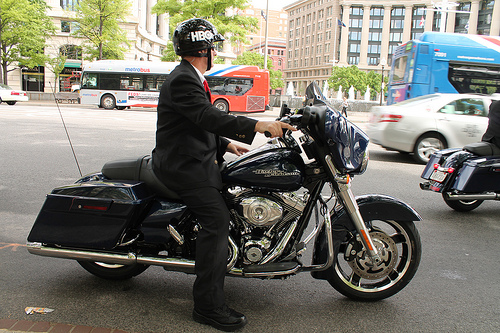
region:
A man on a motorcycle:
[20, 8, 424, 329]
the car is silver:
[373, 96, 495, 150]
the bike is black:
[36, 126, 438, 283]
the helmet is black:
[165, 22, 221, 53]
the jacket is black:
[148, 58, 226, 185]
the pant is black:
[162, 182, 240, 309]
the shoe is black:
[193, 304, 246, 328]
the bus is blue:
[409, 34, 499, 95]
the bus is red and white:
[81, 63, 271, 111]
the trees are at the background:
[3, 2, 384, 94]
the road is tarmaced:
[1, 87, 149, 160]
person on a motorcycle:
[20, 11, 431, 331]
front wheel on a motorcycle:
[308, 190, 427, 310]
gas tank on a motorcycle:
[218, 130, 308, 194]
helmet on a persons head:
[168, 15, 228, 58]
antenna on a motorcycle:
[43, 75, 86, 181]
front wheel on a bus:
[97, 91, 119, 111]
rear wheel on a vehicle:
[411, 130, 452, 166]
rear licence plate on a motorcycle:
[426, 162, 456, 184]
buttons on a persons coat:
[230, 128, 249, 141]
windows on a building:
[343, 2, 386, 67]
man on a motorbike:
[11, 4, 442, 331]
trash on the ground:
[23, 299, 55, 315]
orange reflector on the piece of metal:
[355, 225, 380, 252]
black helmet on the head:
[171, 17, 228, 77]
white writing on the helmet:
[185, 27, 219, 42]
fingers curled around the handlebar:
[253, 111, 296, 141]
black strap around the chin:
[203, 49, 215, 72]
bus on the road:
[58, 43, 298, 120]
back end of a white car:
[1, 80, 28, 107]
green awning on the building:
[53, 60, 85, 70]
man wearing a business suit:
[157, 19, 263, 330]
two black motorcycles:
[39, 95, 499, 312]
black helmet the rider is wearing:
[169, 19, 224, 46]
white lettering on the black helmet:
[190, 29, 214, 43]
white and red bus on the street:
[82, 59, 266, 116]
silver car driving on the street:
[375, 89, 490, 169]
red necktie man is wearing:
[200, 76, 224, 101]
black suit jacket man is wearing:
[151, 67, 252, 182]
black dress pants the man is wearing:
[190, 193, 242, 310]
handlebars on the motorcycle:
[275, 87, 320, 143]